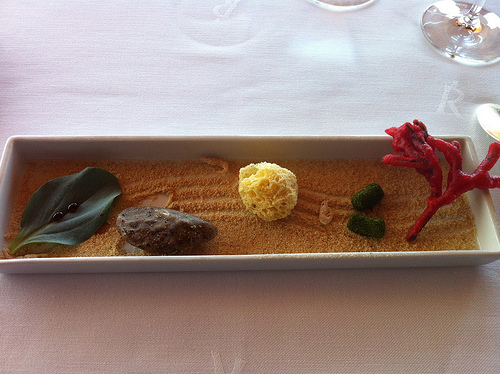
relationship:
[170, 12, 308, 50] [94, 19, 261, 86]
indentation on cloth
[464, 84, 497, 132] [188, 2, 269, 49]
sugar on plate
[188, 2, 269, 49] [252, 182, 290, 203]
plate has yellow